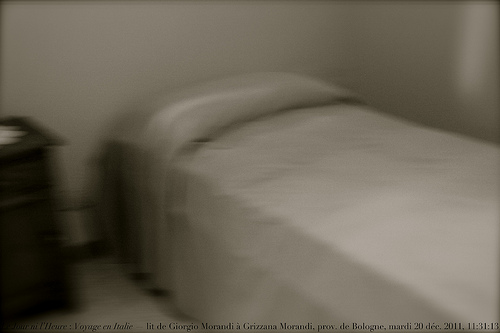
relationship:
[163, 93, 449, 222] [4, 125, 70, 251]
bed near dresser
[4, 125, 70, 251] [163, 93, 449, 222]
dresser near bed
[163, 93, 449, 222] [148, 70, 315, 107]
bed has pillows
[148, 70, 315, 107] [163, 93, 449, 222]
pillows near bed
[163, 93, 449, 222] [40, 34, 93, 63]
bed near wall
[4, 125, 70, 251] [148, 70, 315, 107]
dresser near pillows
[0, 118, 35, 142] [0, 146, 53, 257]
papers on table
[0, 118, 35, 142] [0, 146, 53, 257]
papers near table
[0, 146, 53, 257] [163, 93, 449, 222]
table near bed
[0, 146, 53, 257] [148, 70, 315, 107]
table near pillows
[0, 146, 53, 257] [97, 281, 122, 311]
table near ground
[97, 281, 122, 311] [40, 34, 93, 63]
ground near wall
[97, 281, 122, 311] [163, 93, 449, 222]
ground near bed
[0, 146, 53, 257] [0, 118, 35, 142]
table has papers